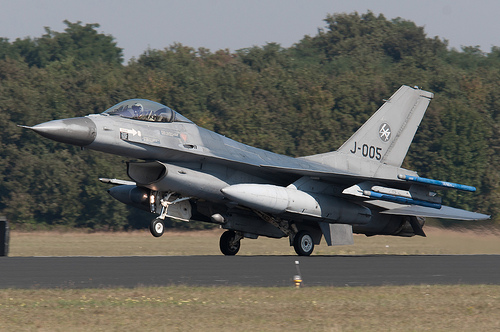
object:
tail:
[337, 85, 434, 168]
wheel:
[149, 219, 165, 237]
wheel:
[219, 230, 240, 255]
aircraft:
[16, 84, 491, 255]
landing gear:
[220, 230, 315, 256]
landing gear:
[150, 190, 193, 237]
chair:
[134, 110, 163, 122]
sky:
[0, 0, 498, 56]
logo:
[378, 123, 392, 142]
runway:
[0, 255, 500, 287]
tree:
[326, 97, 342, 138]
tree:
[2, 103, 38, 121]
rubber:
[296, 235, 301, 250]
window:
[100, 99, 192, 123]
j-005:
[350, 141, 382, 160]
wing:
[259, 164, 476, 203]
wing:
[342, 181, 492, 221]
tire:
[294, 230, 314, 255]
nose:
[17, 117, 98, 147]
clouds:
[251, 5, 284, 21]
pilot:
[128, 102, 143, 119]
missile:
[220, 183, 372, 226]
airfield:
[0, 221, 499, 330]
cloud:
[3, 2, 37, 30]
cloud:
[106, 0, 132, 21]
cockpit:
[101, 98, 196, 132]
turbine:
[220, 183, 374, 224]